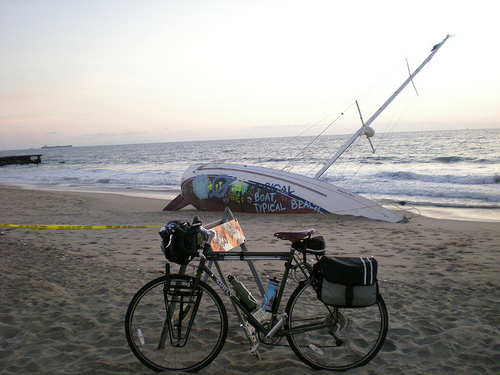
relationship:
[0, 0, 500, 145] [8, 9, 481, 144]
clouds in sky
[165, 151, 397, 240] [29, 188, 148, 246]
boat on beach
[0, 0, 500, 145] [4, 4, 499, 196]
clouds on blue sky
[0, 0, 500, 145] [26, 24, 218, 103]
clouds in blue sky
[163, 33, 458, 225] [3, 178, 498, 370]
sailboat stranded on a beach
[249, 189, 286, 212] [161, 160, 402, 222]
graffiti on a boat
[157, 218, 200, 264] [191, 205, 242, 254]
basket hanging form handlebars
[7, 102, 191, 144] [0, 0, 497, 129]
clouds in sky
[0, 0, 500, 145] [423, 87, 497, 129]
clouds in sky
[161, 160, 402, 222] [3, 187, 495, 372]
boat on sand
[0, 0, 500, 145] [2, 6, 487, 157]
clouds in sky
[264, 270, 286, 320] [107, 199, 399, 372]
bottle on bike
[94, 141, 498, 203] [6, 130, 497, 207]
waves in ocean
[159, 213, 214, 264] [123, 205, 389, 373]
basket on bicycle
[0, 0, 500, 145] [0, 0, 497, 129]
clouds in sky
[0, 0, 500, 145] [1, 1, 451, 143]
clouds in blue sky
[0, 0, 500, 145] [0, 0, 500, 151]
clouds in sky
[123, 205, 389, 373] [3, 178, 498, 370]
bicycle on beach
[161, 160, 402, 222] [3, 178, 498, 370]
boat on beach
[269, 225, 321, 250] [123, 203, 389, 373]
bicycle seat on bicycle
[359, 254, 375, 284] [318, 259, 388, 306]
stripes on a bag